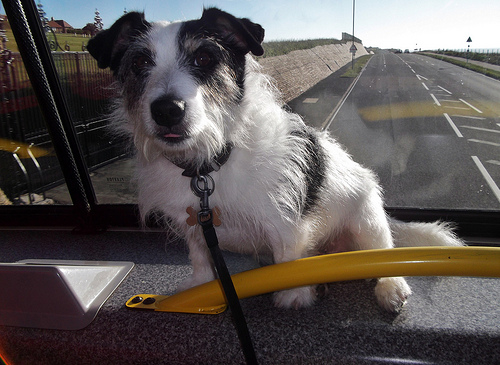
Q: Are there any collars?
A: Yes, there is a collar.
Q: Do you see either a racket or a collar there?
A: Yes, there is a collar.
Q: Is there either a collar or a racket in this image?
A: Yes, there is a collar.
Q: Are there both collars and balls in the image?
A: No, there is a collar but no balls.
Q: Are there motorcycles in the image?
A: No, there are no motorcycles.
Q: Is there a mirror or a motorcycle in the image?
A: No, there are no motorcycles or mirrors.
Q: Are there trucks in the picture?
A: No, there are no trucks.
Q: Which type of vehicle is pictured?
A: The vehicle is a car.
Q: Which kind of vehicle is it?
A: The vehicle is a car.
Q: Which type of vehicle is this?
A: This is a car.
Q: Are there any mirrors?
A: No, there are no mirrors.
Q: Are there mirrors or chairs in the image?
A: No, there are no mirrors or chairs.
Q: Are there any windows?
A: Yes, there is a window.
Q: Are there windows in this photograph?
A: Yes, there is a window.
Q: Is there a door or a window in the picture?
A: Yes, there is a window.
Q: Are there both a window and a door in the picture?
A: No, there is a window but no doors.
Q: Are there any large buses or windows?
A: Yes, there is a large window.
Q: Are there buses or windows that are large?
A: Yes, the window is large.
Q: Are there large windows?
A: Yes, there is a large window.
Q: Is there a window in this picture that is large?
A: Yes, there is a window that is large.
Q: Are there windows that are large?
A: Yes, there is a window that is large.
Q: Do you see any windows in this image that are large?
A: Yes, there is a window that is large.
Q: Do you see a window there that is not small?
A: Yes, there is a large window.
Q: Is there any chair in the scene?
A: No, there are no chairs.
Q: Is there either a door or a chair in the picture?
A: No, there are no chairs or doors.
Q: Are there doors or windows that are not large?
A: No, there is a window but it is large.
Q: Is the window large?
A: Yes, the window is large.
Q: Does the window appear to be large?
A: Yes, the window is large.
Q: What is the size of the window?
A: The window is large.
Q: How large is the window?
A: The window is large.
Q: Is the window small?
A: No, the window is large.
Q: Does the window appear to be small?
A: No, the window is large.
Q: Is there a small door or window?
A: No, there is a window but it is large.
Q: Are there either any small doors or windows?
A: No, there is a window but it is large.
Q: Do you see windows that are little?
A: No, there is a window but it is large.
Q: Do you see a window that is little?
A: No, there is a window but it is large.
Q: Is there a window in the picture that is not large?
A: No, there is a window but it is large.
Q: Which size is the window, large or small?
A: The window is large.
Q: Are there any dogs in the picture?
A: Yes, there is a dog.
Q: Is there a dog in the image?
A: Yes, there is a dog.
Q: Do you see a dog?
A: Yes, there is a dog.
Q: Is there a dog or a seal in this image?
A: Yes, there is a dog.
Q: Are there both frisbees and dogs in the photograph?
A: No, there is a dog but no frisbees.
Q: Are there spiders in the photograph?
A: No, there are no spiders.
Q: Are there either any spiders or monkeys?
A: No, there are no spiders or monkeys.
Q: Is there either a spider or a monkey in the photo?
A: No, there are no spiders or monkeys.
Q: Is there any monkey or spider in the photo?
A: No, there are no spiders or monkeys.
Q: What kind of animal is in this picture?
A: The animal is a dog.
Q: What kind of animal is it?
A: The animal is a dog.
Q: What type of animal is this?
A: That is a dog.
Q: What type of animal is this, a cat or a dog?
A: That is a dog.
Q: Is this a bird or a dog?
A: This is a dog.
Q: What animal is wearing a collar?
A: The dog is wearing a collar.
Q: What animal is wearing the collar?
A: The dog is wearing a collar.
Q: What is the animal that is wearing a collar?
A: The animal is a dog.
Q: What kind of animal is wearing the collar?
A: The animal is a dog.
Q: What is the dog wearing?
A: The dog is wearing a collar.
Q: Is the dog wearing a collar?
A: Yes, the dog is wearing a collar.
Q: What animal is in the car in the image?
A: The dog is in the car.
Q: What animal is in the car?
A: The dog is in the car.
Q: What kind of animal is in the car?
A: The animal is a dog.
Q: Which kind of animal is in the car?
A: The animal is a dog.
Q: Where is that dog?
A: The dog is in the car.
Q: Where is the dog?
A: The dog is in the car.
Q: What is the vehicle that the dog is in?
A: The vehicle is a car.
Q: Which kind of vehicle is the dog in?
A: The dog is in the car.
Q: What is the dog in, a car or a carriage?
A: The dog is in a car.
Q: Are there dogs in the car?
A: Yes, there is a dog in the car.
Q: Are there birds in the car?
A: No, there is a dog in the car.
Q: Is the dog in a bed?
A: No, the dog is in the car.